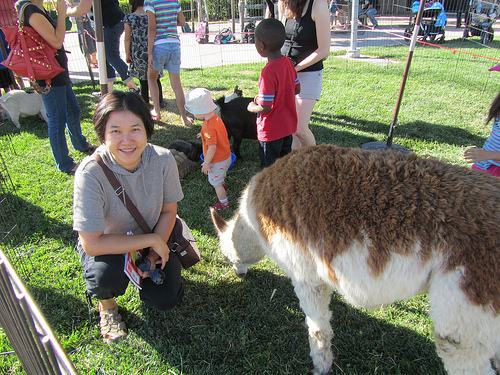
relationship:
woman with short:
[61, 60, 218, 331] [67, 261, 134, 303]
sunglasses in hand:
[135, 255, 165, 290] [135, 238, 184, 280]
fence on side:
[233, 3, 260, 18] [10, 259, 86, 369]